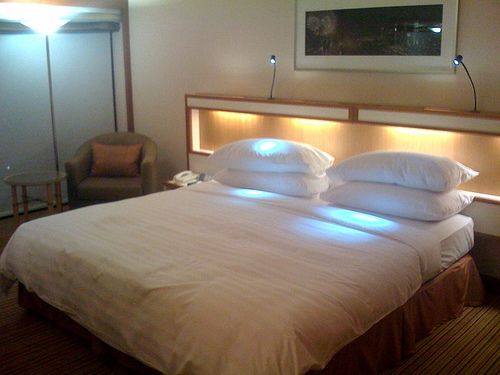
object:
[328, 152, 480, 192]
pillow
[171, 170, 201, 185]
telephone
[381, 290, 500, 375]
rug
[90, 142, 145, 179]
pillow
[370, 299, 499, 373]
ground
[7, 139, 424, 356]
bed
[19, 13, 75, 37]
tall lamp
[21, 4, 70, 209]
floor lamp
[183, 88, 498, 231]
head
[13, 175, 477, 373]
bed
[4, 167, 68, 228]
table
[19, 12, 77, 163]
light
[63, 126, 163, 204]
chair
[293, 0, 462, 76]
picture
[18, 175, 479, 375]
bed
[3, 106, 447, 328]
bed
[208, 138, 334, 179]
pillow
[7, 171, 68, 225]
brown table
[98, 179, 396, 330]
bed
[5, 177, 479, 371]
bed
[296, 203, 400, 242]
lights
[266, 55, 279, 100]
light fixture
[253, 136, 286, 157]
light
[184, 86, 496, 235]
headboard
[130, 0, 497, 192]
white wall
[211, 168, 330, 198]
pillow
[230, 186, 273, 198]
lighting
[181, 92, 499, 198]
headboard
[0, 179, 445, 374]
comforter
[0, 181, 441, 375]
sheet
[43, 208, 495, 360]
bed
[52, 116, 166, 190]
chair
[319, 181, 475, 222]
pillow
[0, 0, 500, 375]
room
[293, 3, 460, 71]
frame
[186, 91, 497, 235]
paneling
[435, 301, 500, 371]
stripes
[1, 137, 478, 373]
bedding